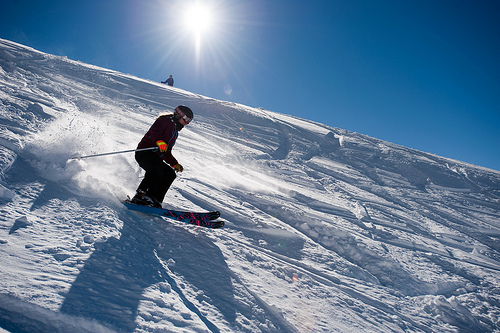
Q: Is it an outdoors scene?
A: Yes, it is outdoors.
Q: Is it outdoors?
A: Yes, it is outdoors.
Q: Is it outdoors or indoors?
A: It is outdoors.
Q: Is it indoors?
A: No, it is outdoors.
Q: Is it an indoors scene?
A: No, it is outdoors.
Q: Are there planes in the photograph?
A: No, there are no planes.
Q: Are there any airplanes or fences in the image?
A: No, there are no airplanes or fences.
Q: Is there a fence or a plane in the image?
A: No, there are no airplanes or fences.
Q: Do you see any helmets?
A: Yes, there is a helmet.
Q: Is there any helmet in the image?
A: Yes, there is a helmet.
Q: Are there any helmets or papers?
A: Yes, there is a helmet.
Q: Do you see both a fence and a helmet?
A: No, there is a helmet but no fences.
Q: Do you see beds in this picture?
A: No, there are no beds.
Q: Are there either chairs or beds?
A: No, there are no beds or chairs.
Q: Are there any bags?
A: No, there are no bags.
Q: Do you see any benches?
A: No, there are no benches.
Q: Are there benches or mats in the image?
A: No, there are no benches or mats.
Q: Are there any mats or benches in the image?
A: No, there are no benches or mats.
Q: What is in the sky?
A: The sun is in the sky.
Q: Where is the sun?
A: The sun is in the sky.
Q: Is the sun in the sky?
A: Yes, the sun is in the sky.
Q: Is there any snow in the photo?
A: Yes, there is snow.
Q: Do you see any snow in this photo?
A: Yes, there is snow.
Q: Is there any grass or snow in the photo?
A: Yes, there is snow.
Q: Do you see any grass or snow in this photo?
A: Yes, there is snow.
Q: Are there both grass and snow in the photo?
A: No, there is snow but no grass.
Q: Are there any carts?
A: No, there are no carts.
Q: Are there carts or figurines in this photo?
A: No, there are no carts or figurines.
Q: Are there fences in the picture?
A: No, there are no fences.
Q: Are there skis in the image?
A: Yes, there are skis.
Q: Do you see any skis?
A: Yes, there are skis.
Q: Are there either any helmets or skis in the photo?
A: Yes, there are skis.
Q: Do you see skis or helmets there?
A: Yes, there are skis.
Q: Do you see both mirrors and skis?
A: No, there are skis but no mirrors.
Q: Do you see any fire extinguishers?
A: No, there are no fire extinguishers.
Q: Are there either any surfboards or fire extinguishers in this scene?
A: No, there are no fire extinguishers or surfboards.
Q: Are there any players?
A: No, there are no players.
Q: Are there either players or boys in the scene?
A: No, there are no players or boys.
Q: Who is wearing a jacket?
A: The man is wearing a jacket.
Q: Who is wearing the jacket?
A: The man is wearing a jacket.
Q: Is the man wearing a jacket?
A: Yes, the man is wearing a jacket.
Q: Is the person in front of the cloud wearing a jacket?
A: Yes, the man is wearing a jacket.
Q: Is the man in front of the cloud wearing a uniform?
A: No, the man is wearing a jacket.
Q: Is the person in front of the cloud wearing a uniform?
A: No, the man is wearing a jacket.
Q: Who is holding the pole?
A: The man is holding the pole.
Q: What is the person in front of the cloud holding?
A: The man is holding the pole.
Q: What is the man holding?
A: The man is holding the pole.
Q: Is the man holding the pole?
A: Yes, the man is holding the pole.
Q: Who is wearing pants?
A: The man is wearing pants.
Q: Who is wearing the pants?
A: The man is wearing pants.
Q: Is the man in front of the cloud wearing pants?
A: Yes, the man is wearing pants.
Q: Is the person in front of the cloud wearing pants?
A: Yes, the man is wearing pants.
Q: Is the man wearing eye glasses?
A: No, the man is wearing pants.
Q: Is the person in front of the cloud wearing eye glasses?
A: No, the man is wearing pants.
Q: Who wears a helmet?
A: The man wears a helmet.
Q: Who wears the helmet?
A: The man wears a helmet.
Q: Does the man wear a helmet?
A: Yes, the man wears a helmet.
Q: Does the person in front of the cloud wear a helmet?
A: Yes, the man wears a helmet.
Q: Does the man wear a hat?
A: No, the man wears a helmet.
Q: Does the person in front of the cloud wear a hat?
A: No, the man wears a helmet.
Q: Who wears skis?
A: The man wears skis.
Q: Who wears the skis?
A: The man wears skis.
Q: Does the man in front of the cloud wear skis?
A: Yes, the man wears skis.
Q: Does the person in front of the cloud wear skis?
A: Yes, the man wears skis.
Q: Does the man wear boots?
A: No, the man wears skis.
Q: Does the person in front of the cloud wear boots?
A: No, the man wears skis.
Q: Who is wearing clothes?
A: The man is wearing clothes.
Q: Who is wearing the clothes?
A: The man is wearing clothes.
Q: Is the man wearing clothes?
A: Yes, the man is wearing clothes.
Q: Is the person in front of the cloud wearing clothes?
A: Yes, the man is wearing clothes.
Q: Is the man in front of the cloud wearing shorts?
A: No, the man is wearing clothes.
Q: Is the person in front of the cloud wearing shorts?
A: No, the man is wearing clothes.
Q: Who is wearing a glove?
A: The man is wearing a glove.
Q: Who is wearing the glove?
A: The man is wearing a glove.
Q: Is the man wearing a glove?
A: Yes, the man is wearing a glove.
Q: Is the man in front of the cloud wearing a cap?
A: No, the man is wearing a glove.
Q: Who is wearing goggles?
A: The man is wearing goggles.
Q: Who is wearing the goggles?
A: The man is wearing goggles.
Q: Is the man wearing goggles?
A: Yes, the man is wearing goggles.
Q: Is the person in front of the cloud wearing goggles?
A: Yes, the man is wearing goggles.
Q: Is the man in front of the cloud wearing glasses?
A: No, the man is wearing goggles.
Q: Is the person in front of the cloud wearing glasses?
A: No, the man is wearing goggles.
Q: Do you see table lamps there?
A: No, there are no table lamps.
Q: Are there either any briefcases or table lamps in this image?
A: No, there are no table lamps or briefcases.